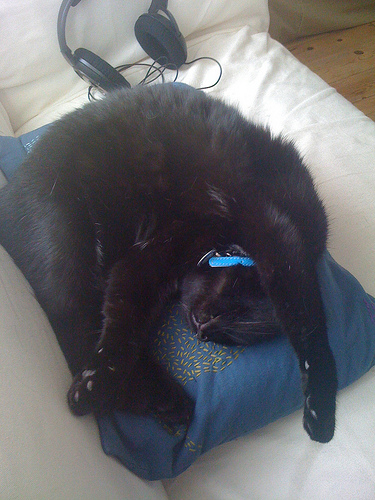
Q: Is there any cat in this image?
A: Yes, there is a cat.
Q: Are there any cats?
A: Yes, there is a cat.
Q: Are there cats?
A: Yes, there is a cat.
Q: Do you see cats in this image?
A: Yes, there is a cat.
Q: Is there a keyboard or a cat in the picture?
A: Yes, there is a cat.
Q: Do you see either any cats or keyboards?
A: Yes, there is a cat.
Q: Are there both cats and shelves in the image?
A: No, there is a cat but no shelves.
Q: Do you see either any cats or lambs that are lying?
A: Yes, the cat is lying.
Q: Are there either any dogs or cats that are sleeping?
A: Yes, the cat is sleeping.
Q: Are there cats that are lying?
A: Yes, there is a cat that is lying.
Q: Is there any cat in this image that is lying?
A: Yes, there is a cat that is lying.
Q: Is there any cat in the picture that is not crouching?
A: Yes, there is a cat that is lying.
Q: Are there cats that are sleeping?
A: Yes, there is a cat that is sleeping.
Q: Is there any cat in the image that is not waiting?
A: Yes, there is a cat that is sleeping.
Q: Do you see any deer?
A: No, there are no deer.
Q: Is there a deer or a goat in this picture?
A: No, there are no deer or goats.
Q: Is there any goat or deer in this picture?
A: No, there are no deer or goats.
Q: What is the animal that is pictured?
A: The animal is a cat.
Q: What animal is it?
A: The animal is a cat.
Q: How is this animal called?
A: This is a cat.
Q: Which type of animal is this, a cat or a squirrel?
A: This is a cat.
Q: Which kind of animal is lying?
A: The animal is a cat.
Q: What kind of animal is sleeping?
A: The animal is a cat.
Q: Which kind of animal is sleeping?
A: The animal is a cat.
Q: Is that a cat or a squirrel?
A: That is a cat.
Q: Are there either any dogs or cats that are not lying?
A: No, there is a cat but it is lying.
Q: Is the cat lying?
A: Yes, the cat is lying.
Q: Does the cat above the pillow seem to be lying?
A: Yes, the cat is lying.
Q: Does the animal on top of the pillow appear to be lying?
A: Yes, the cat is lying.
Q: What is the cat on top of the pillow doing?
A: The cat is lying.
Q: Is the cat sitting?
A: No, the cat is lying.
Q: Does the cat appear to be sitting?
A: No, the cat is lying.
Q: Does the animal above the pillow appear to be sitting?
A: No, the cat is lying.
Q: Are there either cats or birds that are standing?
A: No, there is a cat but it is lying.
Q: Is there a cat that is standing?
A: No, there is a cat but it is lying.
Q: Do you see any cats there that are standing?
A: No, there is a cat but it is lying.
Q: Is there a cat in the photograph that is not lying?
A: No, there is a cat but it is lying.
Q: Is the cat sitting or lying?
A: The cat is lying.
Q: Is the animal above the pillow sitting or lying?
A: The cat is lying.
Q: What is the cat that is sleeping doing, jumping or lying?
A: The cat is lying.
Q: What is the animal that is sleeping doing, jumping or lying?
A: The cat is lying.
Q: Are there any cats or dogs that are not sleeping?
A: No, there is a cat but it is sleeping.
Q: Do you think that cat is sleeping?
A: Yes, the cat is sleeping.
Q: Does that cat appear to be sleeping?
A: Yes, the cat is sleeping.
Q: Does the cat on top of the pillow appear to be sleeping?
A: Yes, the cat is sleeping.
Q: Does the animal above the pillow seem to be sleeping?
A: Yes, the cat is sleeping.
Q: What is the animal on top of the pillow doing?
A: The cat is sleeping.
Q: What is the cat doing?
A: The cat is sleeping.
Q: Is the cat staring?
A: No, the cat is sleeping.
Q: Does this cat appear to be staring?
A: No, the cat is sleeping.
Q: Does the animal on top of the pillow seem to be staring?
A: No, the cat is sleeping.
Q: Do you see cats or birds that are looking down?
A: No, there is a cat but it is sleeping.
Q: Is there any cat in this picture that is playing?
A: No, there is a cat but it is sleeping.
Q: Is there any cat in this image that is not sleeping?
A: No, there is a cat but it is sleeping.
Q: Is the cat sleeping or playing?
A: The cat is sleeping.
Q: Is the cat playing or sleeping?
A: The cat is sleeping.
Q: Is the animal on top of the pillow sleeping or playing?
A: The cat is sleeping.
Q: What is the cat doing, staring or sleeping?
A: The cat is sleeping.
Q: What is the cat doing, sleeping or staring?
A: The cat is sleeping.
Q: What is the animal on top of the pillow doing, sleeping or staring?
A: The cat is sleeping.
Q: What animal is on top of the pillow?
A: The cat is on top of the pillow.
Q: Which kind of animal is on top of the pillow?
A: The animal is a cat.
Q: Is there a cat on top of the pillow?
A: Yes, there is a cat on top of the pillow.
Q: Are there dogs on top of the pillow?
A: No, there is a cat on top of the pillow.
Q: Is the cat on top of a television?
A: No, the cat is on top of a pillow.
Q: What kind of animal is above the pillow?
A: The animal is a cat.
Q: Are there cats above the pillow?
A: Yes, there is a cat above the pillow.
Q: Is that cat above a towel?
A: No, the cat is above a pillow.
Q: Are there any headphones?
A: Yes, there are headphones.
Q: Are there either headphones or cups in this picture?
A: Yes, there are headphones.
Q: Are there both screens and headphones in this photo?
A: No, there are headphones but no screens.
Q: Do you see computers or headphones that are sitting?
A: Yes, the headphones are sitting.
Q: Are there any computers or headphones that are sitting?
A: Yes, the headphones are sitting.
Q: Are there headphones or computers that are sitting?
A: Yes, the headphones are sitting.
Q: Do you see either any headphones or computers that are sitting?
A: Yes, the headphones are sitting.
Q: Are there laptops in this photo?
A: No, there are no laptops.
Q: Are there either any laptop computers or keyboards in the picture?
A: No, there are no laptop computers or keyboards.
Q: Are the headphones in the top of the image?
A: Yes, the headphones are in the top of the image.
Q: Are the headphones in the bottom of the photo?
A: No, the headphones are in the top of the image.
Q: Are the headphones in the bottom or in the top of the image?
A: The headphones are in the top of the image.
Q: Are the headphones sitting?
A: Yes, the headphones are sitting.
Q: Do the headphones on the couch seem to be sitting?
A: Yes, the headphones are sitting.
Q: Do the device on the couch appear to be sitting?
A: Yes, the headphones are sitting.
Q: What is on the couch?
A: The headphones are on the couch.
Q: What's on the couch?
A: The headphones are on the couch.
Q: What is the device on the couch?
A: The device is headphones.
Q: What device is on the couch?
A: The device is headphones.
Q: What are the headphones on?
A: The headphones are on the couch.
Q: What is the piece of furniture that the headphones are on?
A: The piece of furniture is a couch.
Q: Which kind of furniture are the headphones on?
A: The headphones are on the couch.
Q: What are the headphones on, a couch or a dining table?
A: The headphones are on a couch.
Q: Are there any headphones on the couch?
A: Yes, there are headphones on the couch.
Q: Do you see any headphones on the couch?
A: Yes, there are headphones on the couch.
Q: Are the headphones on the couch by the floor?
A: Yes, the headphones are on the couch.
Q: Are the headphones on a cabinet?
A: No, the headphones are on the couch.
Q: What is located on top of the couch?
A: The headphones are on top of the couch.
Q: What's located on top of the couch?
A: The headphones are on top of the couch.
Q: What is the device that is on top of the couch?
A: The device is headphones.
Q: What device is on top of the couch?
A: The device is headphones.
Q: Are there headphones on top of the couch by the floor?
A: Yes, there are headphones on top of the couch.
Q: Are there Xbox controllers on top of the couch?
A: No, there are headphones on top of the couch.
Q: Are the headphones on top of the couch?
A: Yes, the headphones are on top of the couch.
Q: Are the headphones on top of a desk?
A: No, the headphones are on top of the couch.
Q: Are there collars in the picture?
A: Yes, there is a collar.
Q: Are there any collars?
A: Yes, there is a collar.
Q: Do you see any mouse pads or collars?
A: Yes, there is a collar.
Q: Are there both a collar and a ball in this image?
A: No, there is a collar but no balls.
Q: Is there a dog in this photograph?
A: No, there are no dogs.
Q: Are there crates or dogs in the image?
A: No, there are no dogs or crates.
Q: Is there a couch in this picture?
A: Yes, there is a couch.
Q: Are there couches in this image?
A: Yes, there is a couch.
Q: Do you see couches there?
A: Yes, there is a couch.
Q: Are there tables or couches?
A: Yes, there is a couch.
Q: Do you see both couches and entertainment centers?
A: No, there is a couch but no entertainment centers.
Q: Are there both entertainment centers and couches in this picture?
A: No, there is a couch but no entertainment centers.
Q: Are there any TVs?
A: No, there are no tvs.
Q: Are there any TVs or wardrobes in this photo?
A: No, there are no TVs or wardrobes.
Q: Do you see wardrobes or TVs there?
A: No, there are no TVs or wardrobes.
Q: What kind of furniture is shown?
A: The furniture is a couch.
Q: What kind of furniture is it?
A: The piece of furniture is a couch.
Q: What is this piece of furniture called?
A: This is a couch.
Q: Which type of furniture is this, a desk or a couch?
A: This is a couch.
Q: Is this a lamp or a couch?
A: This is a couch.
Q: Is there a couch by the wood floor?
A: Yes, there is a couch by the floor.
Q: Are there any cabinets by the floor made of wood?
A: No, there is a couch by the floor.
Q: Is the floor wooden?
A: Yes, the floor is wooden.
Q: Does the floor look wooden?
A: Yes, the floor is wooden.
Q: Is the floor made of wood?
A: Yes, the floor is made of wood.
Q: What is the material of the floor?
A: The floor is made of wood.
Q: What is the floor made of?
A: The floor is made of wood.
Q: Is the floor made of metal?
A: No, the floor is made of wood.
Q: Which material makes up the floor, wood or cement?
A: The floor is made of wood.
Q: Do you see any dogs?
A: No, there are no dogs.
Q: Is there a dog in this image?
A: No, there are no dogs.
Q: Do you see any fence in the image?
A: No, there are no fences.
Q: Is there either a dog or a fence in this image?
A: No, there are no fences or dogs.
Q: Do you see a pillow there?
A: Yes, there is a pillow.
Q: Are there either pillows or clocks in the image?
A: Yes, there is a pillow.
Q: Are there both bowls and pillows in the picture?
A: No, there is a pillow but no bowls.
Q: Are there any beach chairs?
A: No, there are no beach chairs.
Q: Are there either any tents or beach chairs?
A: No, there are no beach chairs or tents.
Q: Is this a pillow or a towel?
A: This is a pillow.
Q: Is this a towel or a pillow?
A: This is a pillow.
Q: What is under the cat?
A: The pillow is under the cat.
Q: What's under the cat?
A: The pillow is under the cat.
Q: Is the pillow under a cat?
A: Yes, the pillow is under a cat.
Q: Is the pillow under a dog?
A: No, the pillow is under a cat.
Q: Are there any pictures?
A: No, there are no pictures.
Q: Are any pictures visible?
A: No, there are no pictures.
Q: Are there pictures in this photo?
A: No, there are no pictures.